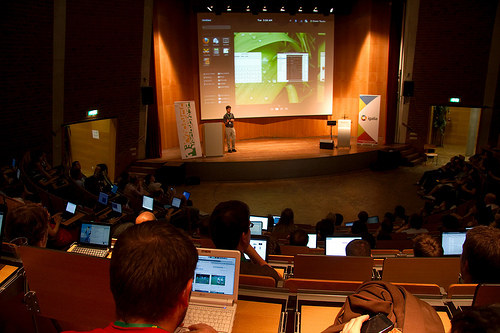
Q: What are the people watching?
A: A presentation.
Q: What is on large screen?
A: Images and text.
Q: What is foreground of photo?
A: Group of people in a classroom.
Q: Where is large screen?
A: On back wall.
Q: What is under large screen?
A: A stage.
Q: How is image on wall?
A: A projector.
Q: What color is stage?
A: Brown.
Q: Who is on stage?
A: One man.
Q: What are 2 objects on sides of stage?
A: Advertisements.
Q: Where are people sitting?
A: On bench.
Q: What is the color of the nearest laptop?
A: White.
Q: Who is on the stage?
A: A man.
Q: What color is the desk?
A: Brown.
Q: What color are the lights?
A: White.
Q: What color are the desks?
A: Brown.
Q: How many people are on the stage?
A: One.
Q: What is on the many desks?
A: Laptop computers.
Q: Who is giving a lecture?
A: Speaker on stage.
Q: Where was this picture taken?
A: Inside a large room.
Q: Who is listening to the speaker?
A: People in their seats.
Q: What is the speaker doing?
A: Giving a lecture.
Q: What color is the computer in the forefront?
A: White.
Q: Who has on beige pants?
A: The speaker.